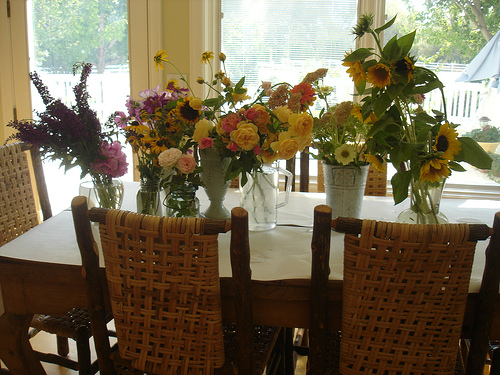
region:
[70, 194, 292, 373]
A dining room chair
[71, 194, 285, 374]
The chair is brown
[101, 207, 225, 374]
Back of the chair is wicker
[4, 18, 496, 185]
A bunch of flowers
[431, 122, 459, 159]
The flower is yellow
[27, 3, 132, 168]
A window to the outside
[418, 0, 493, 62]
Tree in the background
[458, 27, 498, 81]
Part of an umbrella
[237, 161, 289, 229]
A clear jar of water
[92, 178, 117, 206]
The stems are green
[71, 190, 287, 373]
a wooden dining room chair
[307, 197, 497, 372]
a wooden dining room chair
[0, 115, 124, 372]
a wooden dining room chair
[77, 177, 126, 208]
a clear flower vase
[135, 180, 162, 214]
a clear flower vase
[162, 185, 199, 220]
a clear flower vase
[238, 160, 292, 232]
a clear flower vase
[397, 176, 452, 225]
a clear flower vase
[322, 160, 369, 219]
a metal flower vase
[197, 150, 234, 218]
a green flower vase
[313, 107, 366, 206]
the flowers are in the vases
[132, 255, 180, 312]
the chair is woven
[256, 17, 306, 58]
the blind is open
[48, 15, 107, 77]
the window has no blind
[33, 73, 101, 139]
the flowers are purple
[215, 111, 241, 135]
the flower is pink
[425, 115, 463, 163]
the flower is yellow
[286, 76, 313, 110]
the flower is orange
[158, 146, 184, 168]
the flower is white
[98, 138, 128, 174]
the flower is lavender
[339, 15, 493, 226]
a vase full of flowers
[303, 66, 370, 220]
a vase full of flowers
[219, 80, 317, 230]
a vase full of flowers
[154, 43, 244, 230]
a vase full of flowers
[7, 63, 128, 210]
a vase full of flowers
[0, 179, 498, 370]
a dining room table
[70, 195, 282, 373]
a dining room chair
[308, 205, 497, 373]
a dining room chair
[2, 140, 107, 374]
a dining room chair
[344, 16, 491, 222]
a vase of sunflowers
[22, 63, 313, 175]
Flowers in the photo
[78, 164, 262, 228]
Vases on the table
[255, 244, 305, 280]
A table in the photo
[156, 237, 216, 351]
A wooden chair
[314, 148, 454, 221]
Vases with flowers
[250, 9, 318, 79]
Glass panes in the photo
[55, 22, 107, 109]
A window in the room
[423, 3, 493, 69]
A tree in the photo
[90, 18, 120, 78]
a tree trunk in the photo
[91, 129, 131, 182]
Pink flower on the vase